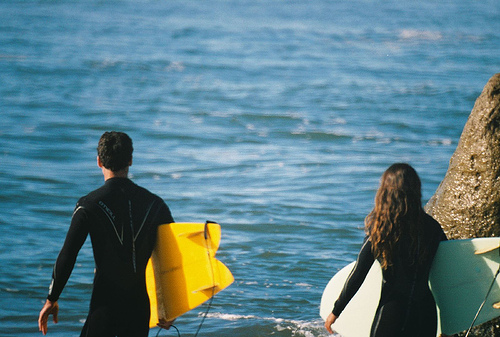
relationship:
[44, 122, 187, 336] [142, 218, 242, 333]
boy carrying surfboard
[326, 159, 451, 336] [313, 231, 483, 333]
girl carrying surfboard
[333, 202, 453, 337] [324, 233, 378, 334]
suit has arm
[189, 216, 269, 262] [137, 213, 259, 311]
strings on surf board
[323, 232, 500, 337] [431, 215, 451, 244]
board under arm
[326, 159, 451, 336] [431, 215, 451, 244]
girl has arm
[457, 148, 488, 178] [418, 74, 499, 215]
holes in rock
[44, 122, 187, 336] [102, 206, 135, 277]
boy in wet suit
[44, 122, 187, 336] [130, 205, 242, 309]
boy with surf board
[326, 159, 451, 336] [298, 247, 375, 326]
girl with surf board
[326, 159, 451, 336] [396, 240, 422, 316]
girl in wet suit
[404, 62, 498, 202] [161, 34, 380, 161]
rock near water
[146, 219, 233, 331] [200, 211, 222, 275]
board with strap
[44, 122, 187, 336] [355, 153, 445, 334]
boy about to surf with woman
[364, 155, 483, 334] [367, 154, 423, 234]
girl with hair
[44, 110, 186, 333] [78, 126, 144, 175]
boy with hair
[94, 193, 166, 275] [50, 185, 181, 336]
design on suit